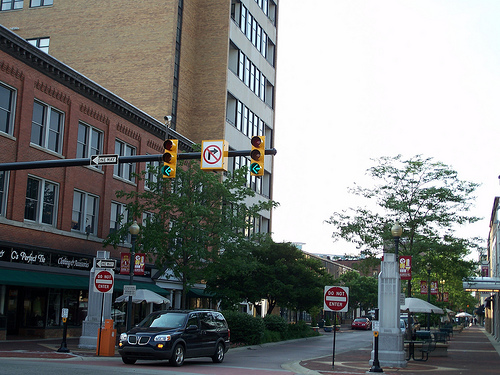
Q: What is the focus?
A: Intersection signs.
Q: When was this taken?
A: Daytime.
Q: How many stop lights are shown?
A: 2.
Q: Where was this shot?
A: Intersection.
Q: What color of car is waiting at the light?
A: Black.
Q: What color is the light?
A: Green.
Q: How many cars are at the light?
A: 1.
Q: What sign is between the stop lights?
A: No right turn.